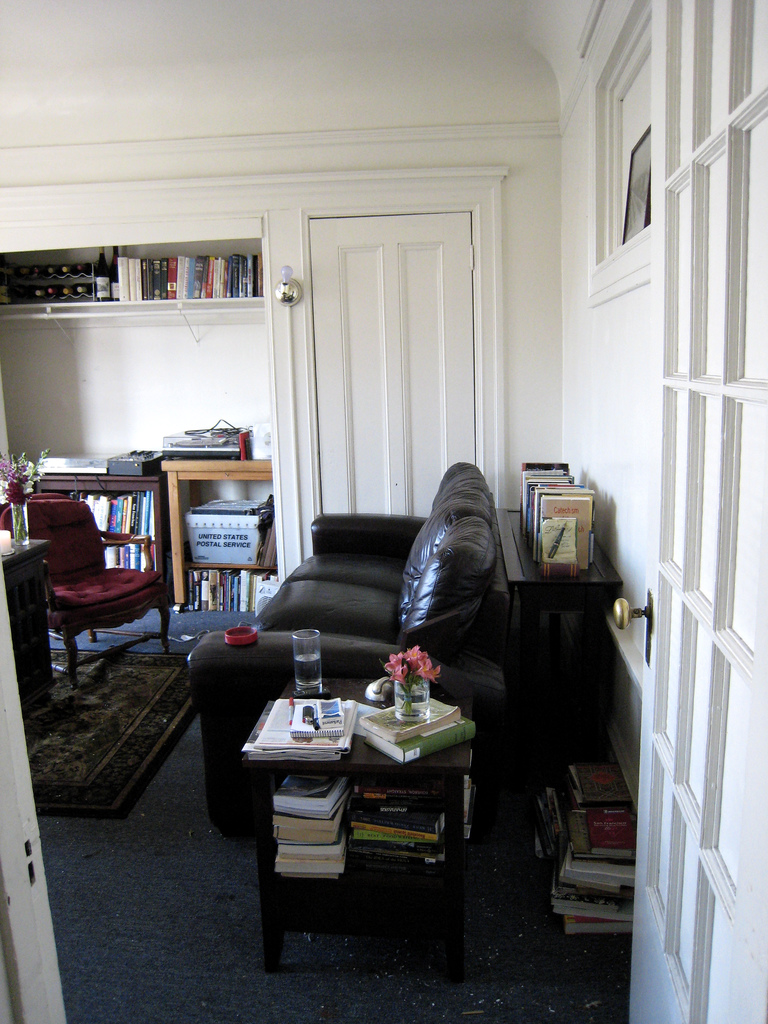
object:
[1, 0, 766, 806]
wall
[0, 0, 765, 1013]
building